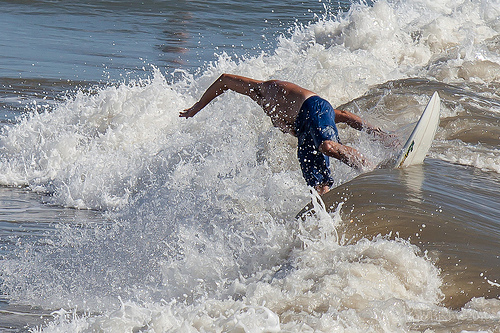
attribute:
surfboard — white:
[404, 86, 439, 171]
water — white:
[0, 2, 480, 152]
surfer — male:
[177, 72, 384, 198]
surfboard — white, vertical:
[390, 89, 442, 170]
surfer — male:
[384, 87, 446, 178]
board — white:
[390, 88, 447, 173]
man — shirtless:
[171, 60, 381, 230]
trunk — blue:
[293, 97, 338, 187]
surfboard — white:
[394, 91, 439, 167]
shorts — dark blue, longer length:
[287, 97, 340, 186]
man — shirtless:
[174, 63, 374, 203]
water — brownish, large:
[371, 174, 497, 267]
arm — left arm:
[189, 70, 263, 112]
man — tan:
[158, 65, 398, 195]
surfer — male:
[180, 72, 400, 194]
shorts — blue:
[295, 95, 342, 186]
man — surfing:
[180, 71, 401, 196]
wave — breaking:
[0, 0, 499, 330]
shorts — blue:
[290, 96, 332, 186]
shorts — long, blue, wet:
[289, 99, 339, 192]